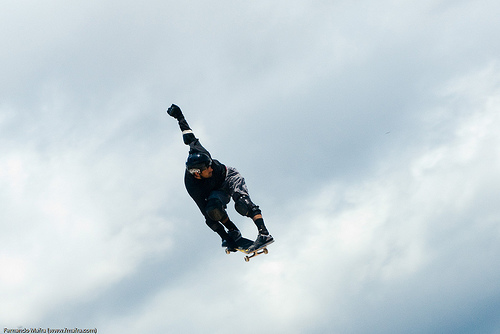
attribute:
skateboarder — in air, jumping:
[167, 99, 276, 260]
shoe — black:
[247, 233, 275, 249]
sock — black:
[248, 215, 272, 236]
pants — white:
[209, 167, 248, 205]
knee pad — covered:
[234, 193, 254, 213]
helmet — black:
[190, 151, 212, 170]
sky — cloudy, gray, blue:
[2, 6, 500, 332]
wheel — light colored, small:
[245, 252, 252, 264]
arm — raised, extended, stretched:
[169, 98, 213, 158]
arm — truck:
[246, 250, 266, 257]